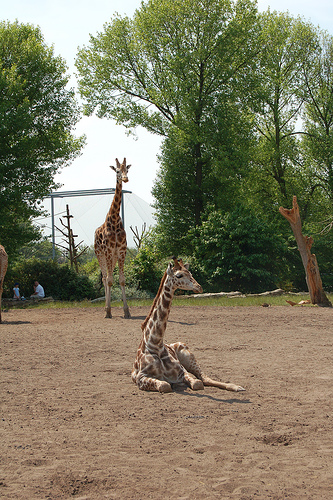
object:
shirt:
[12, 286, 20, 299]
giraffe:
[130, 255, 249, 395]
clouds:
[0, 0, 333, 247]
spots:
[177, 280, 181, 285]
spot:
[105, 246, 112, 255]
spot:
[147, 320, 154, 331]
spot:
[115, 228, 121, 233]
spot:
[115, 222, 120, 228]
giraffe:
[94, 157, 134, 320]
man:
[29, 278, 45, 300]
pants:
[29, 292, 39, 300]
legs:
[188, 362, 237, 393]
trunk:
[278, 193, 333, 308]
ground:
[1, 291, 333, 497]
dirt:
[0, 308, 333, 499]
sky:
[0, 0, 333, 246]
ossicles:
[114, 155, 120, 167]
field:
[0, 287, 333, 497]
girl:
[11, 284, 22, 300]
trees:
[74, 0, 333, 291]